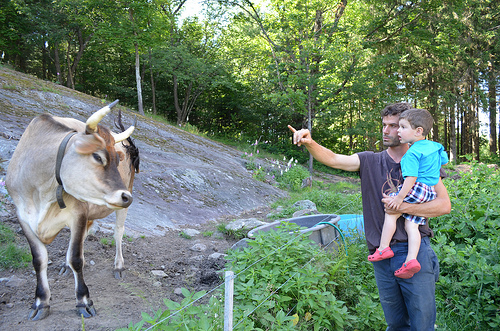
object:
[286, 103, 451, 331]
man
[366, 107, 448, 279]
kid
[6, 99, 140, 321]
cow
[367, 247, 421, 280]
shoes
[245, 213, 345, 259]
bucket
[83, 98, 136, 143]
horns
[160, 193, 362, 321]
fence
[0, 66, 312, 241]
hill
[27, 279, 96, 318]
hooves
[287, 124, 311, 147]
hand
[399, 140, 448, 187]
shirt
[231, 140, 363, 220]
grass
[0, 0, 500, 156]
leaves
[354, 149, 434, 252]
shirt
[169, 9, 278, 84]
sun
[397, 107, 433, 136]
hair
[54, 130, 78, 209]
collar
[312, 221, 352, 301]
hose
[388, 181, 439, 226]
shorts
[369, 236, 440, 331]
jeans